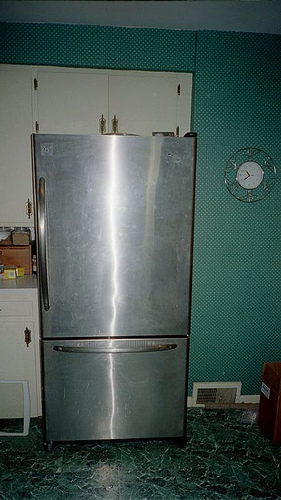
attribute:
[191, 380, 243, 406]
vent — white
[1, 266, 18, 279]
box — yellow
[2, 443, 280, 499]
floor — green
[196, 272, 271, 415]
paper — green, white, wall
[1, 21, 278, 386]
wall paper — green, white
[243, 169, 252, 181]
handles — black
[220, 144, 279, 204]
clock — circular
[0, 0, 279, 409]
wall paper — green, white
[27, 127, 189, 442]
refrigerator — silver, stainless steel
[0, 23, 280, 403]
wallpaper — green, white, wall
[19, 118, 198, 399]
fridge — silver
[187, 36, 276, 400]
wall paper — green, white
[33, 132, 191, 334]
refrigerator door — silver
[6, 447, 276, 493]
floor — teal, tiled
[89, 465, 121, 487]
spot — worn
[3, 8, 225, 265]
area — kitchen area